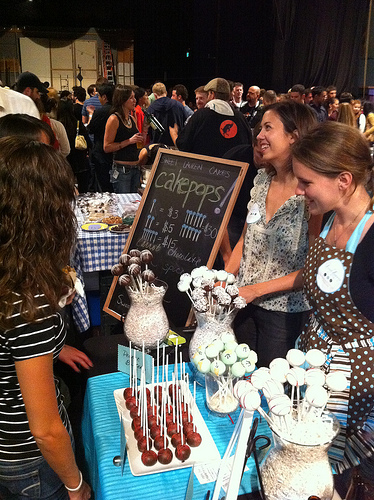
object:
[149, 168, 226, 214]
cakepops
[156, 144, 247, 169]
trim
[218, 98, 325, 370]
female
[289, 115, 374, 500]
female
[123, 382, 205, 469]
cakes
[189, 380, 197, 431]
sticks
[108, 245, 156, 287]
cakepops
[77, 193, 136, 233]
food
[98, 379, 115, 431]
table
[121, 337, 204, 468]
dessert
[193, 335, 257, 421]
dessert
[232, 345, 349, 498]
dessert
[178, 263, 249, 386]
dessert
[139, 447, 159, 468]
dessert balls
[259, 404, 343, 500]
vase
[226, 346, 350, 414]
dessert balls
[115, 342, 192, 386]
card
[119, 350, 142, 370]
name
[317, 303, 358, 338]
dots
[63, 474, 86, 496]
wrist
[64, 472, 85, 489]
bracelet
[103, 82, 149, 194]
woman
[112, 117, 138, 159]
tanktop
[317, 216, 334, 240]
strap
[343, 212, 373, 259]
strap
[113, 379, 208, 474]
tray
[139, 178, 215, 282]
information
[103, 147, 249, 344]
board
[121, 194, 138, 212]
table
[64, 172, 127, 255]
items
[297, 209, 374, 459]
apron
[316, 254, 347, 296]
button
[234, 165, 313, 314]
blouse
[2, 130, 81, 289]
head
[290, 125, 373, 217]
head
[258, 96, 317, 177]
head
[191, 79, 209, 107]
person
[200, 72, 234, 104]
head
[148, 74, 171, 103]
head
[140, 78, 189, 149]
person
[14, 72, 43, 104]
person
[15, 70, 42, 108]
head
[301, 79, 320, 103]
head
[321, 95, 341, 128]
person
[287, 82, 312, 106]
person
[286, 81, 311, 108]
head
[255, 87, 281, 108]
head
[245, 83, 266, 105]
person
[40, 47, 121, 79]
wall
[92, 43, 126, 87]
ladder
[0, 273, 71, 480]
shirt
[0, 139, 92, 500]
lady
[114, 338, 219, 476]
cake pops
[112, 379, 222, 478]
plate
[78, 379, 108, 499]
table cloth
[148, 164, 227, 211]
sign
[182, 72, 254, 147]
man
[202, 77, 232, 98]
hat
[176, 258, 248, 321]
cake pops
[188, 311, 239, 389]
vase